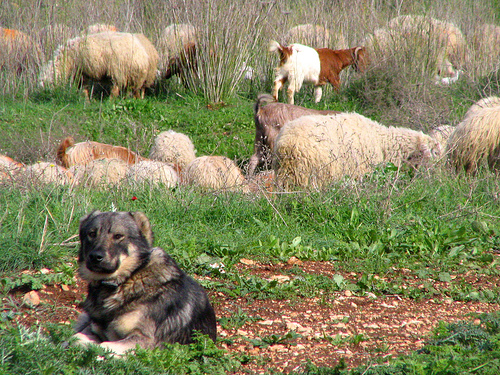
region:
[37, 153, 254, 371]
a sheep dog laying down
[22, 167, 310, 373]
a dog laying down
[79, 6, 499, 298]
sheep in the grass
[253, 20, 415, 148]
a goat in the field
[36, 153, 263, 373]
an alert dog laying down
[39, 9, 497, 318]
goat in tall grass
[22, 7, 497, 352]
sheep standing and laying down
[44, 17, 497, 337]
sheep outside during the day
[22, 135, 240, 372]
dog guarding sheep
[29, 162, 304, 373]
dog guarding sheep during the day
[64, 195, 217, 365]
a sheep dog resting in the grass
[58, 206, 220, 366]
a tan and black dog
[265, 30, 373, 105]
a standing brown and white goat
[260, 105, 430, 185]
a shaggy tan sheep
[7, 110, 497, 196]
a row of sheep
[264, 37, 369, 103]
a goat grazing in the grass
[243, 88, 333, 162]
a dark brown goat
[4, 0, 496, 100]
sheep in the tall grass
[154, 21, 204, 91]
a sheep grazing in the grass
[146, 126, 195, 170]
a sheep grazing in the grass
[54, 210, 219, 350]
black and tan dog resting on ground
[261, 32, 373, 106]
brown and white sheep standing in tall grass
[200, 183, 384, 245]
tall green grass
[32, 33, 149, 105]
yellow sheep grazing on grass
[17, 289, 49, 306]
tan rock on dirt ground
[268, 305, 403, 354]
patch of dirt and rock on ground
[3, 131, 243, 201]
group of sheep lying in grass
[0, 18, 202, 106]
group of sheep standing and grazing on tall grass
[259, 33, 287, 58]
short sheep tail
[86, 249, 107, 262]
black dog nose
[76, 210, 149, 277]
the head of the dog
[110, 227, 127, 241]
the eye of the dog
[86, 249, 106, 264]
the nose of the dog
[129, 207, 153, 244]
the ear of the dog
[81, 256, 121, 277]
the mouth of the dog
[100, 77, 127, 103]
the leg of a sheep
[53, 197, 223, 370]
a dog on the ground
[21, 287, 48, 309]
a brown rock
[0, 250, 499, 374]
a patch of dirt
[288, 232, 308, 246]
a green leaf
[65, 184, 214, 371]
the dog is brown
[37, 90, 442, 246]
the sheep are sitting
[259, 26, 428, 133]
the goat is eating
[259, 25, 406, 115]
the goat is brown and white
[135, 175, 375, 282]
the grass is green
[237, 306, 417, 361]
the ground is brown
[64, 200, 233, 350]
the dog is sitting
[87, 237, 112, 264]
the nose is black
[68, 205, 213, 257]
the ears are gray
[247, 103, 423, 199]
the sheep are beige